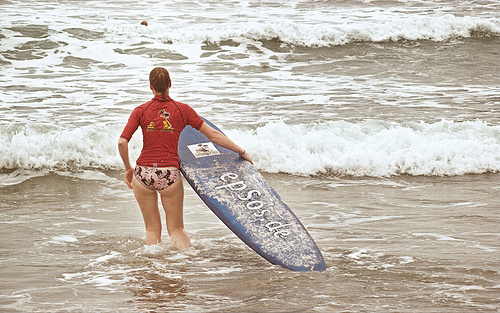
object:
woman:
[116, 67, 253, 252]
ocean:
[0, 0, 497, 312]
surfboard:
[175, 114, 324, 272]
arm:
[185, 106, 243, 154]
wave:
[108, 14, 499, 60]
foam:
[0, 0, 499, 312]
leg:
[130, 172, 162, 249]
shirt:
[117, 95, 205, 168]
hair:
[147, 66, 172, 102]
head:
[140, 20, 148, 27]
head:
[148, 66, 173, 96]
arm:
[116, 108, 141, 170]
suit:
[119, 95, 205, 191]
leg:
[157, 178, 192, 250]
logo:
[184, 141, 221, 159]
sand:
[178, 150, 256, 180]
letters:
[272, 229, 291, 239]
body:
[117, 94, 255, 248]